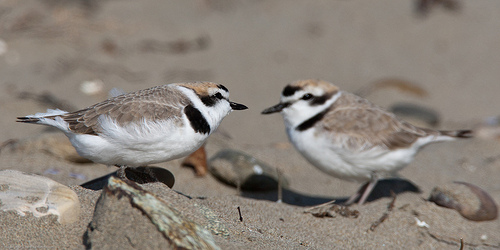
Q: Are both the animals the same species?
A: Yes, all the animals are birds.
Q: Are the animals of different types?
A: No, all the animals are birds.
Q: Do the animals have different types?
A: No, all the animals are birds.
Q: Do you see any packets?
A: No, there are no packets.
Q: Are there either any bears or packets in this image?
A: No, there are no packets or bears.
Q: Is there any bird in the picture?
A: Yes, there is a bird.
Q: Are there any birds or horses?
A: Yes, there is a bird.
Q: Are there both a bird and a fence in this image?
A: No, there is a bird but no fences.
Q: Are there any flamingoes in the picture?
A: No, there are no flamingoes.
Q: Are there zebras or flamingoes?
A: No, there are no flamingoes or zebras.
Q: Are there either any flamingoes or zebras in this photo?
A: No, there are no flamingoes or zebras.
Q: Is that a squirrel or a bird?
A: That is a bird.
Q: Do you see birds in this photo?
A: Yes, there is a bird.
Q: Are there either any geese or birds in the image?
A: Yes, there is a bird.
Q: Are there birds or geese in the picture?
A: Yes, there is a bird.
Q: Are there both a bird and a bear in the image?
A: No, there is a bird but no bears.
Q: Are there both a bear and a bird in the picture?
A: No, there is a bird but no bears.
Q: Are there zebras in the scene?
A: No, there are no zebras.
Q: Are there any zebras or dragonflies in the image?
A: No, there are no zebras or dragonflies.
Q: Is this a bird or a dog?
A: This is a bird.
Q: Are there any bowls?
A: No, there are no bowls.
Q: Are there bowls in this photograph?
A: No, there are no bowls.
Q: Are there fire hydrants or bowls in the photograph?
A: No, there are no bowls or fire hydrants.